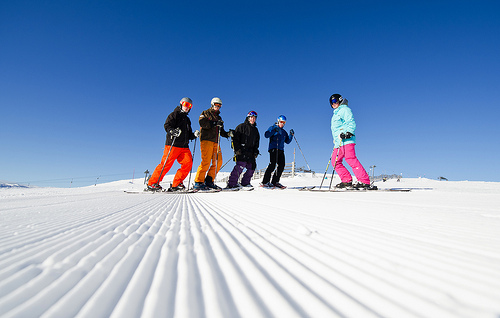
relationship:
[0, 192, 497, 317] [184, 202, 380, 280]
tracks in snow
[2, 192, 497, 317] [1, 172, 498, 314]
tracks in snow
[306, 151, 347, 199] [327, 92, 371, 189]
ski pole held by people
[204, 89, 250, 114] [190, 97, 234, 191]
white helmet on skier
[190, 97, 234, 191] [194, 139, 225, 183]
skier wearing pants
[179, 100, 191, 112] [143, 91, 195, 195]
goggles on skier